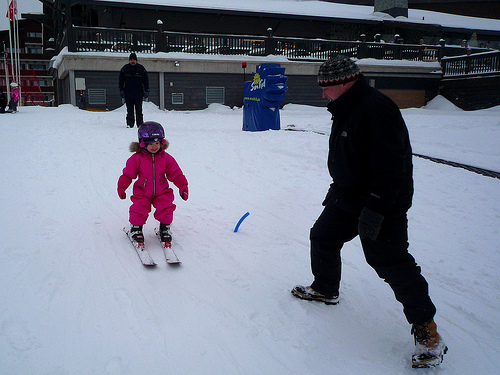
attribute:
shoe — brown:
[404, 317, 450, 370]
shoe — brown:
[293, 264, 350, 308]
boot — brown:
[292, 270, 343, 308]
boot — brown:
[404, 311, 447, 364]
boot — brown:
[290, 273, 346, 313]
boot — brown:
[398, 311, 452, 370]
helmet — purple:
[134, 120, 169, 142]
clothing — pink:
[111, 150, 185, 204]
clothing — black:
[118, 65, 150, 111]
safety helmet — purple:
[137, 117, 167, 144]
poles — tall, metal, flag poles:
[0, 9, 26, 104]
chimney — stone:
[365, 0, 422, 23]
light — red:
[238, 57, 249, 71]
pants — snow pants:
[122, 86, 144, 127]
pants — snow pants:
[281, 185, 462, 353]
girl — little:
[111, 112, 186, 247]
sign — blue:
[232, 49, 292, 145]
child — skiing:
[113, 113, 191, 248]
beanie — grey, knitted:
[306, 44, 368, 91]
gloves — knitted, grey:
[345, 204, 392, 251]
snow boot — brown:
[287, 273, 346, 313]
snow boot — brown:
[391, 310, 451, 370]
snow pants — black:
[351, 198, 446, 329]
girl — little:
[111, 117, 191, 241]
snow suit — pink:
[109, 146, 199, 231]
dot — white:
[319, 59, 334, 69]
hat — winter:
[307, 49, 373, 89]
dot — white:
[327, 60, 334, 68]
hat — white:
[314, 51, 354, 80]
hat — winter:
[314, 52, 354, 84]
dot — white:
[324, 59, 332, 67]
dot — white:
[335, 65, 346, 75]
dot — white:
[330, 60, 340, 73]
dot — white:
[332, 62, 345, 67]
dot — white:
[339, 60, 346, 68]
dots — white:
[321, 62, 345, 80]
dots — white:
[325, 57, 345, 69]